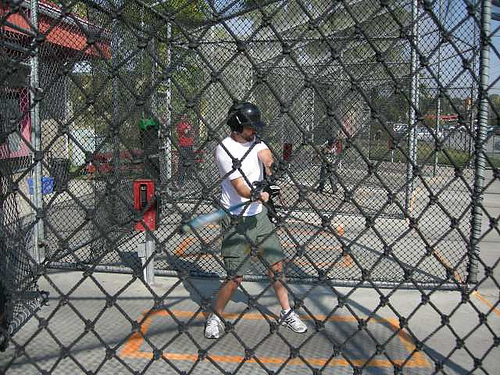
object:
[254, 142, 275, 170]
arm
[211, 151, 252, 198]
arm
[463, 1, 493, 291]
pole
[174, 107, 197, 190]
man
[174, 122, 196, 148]
shirt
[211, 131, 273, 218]
shirt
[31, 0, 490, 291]
cages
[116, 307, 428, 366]
batter's box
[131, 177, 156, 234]
box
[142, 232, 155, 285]
post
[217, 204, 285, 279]
shorts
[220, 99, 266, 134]
helmet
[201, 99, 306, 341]
batter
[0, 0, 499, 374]
fence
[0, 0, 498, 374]
cage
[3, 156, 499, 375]
pavement